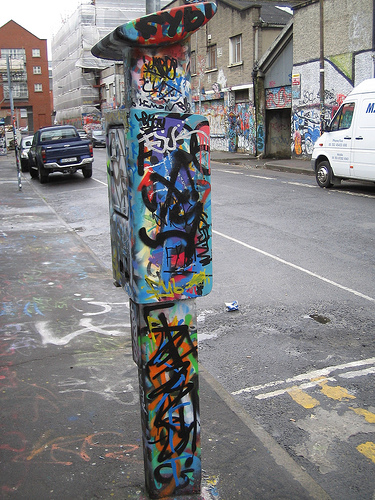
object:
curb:
[0, 151, 338, 498]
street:
[0, 146, 375, 499]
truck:
[27, 125, 94, 186]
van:
[311, 71, 375, 192]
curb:
[263, 156, 316, 178]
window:
[227, 30, 244, 70]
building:
[157, 0, 294, 162]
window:
[186, 50, 199, 78]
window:
[30, 45, 42, 60]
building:
[0, 18, 55, 137]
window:
[31, 63, 45, 77]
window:
[32, 83, 44, 93]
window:
[3, 83, 31, 104]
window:
[204, 40, 218, 74]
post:
[85, 0, 219, 500]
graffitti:
[88, 0, 222, 498]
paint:
[286, 384, 322, 411]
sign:
[291, 68, 301, 102]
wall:
[289, 0, 375, 166]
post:
[3, 55, 22, 192]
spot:
[309, 309, 334, 328]